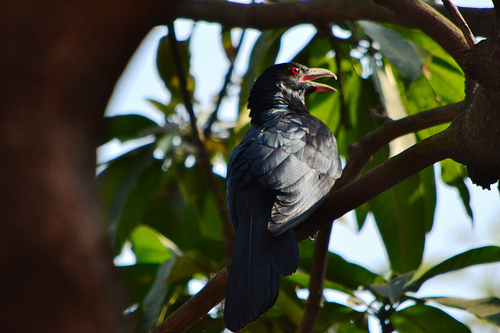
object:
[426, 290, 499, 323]
tree leaves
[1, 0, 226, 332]
tree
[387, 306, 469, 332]
green leaves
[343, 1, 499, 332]
green tree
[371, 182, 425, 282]
leaves on tree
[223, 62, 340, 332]
bird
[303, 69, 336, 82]
beak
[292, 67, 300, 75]
red eye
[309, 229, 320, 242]
foot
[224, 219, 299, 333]
feathers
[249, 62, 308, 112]
feathers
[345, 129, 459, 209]
brown branch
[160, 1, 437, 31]
branches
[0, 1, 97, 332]
large trunk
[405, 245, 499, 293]
leaves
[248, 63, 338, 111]
head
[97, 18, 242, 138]
blue sky